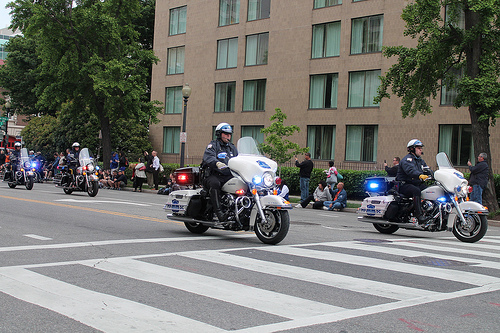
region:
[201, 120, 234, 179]
this is a policeman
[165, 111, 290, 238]
the policeman is on a motorcycle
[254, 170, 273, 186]
the front lights are on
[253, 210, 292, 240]
the whee is small in size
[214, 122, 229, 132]
the police is wearing a helmet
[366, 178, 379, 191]
the side light is on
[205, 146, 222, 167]
the jacket is black in color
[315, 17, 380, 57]
the windows are closed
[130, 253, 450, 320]
this is a zebra crossing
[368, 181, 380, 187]
the light is blue in color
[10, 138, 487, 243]
the men are on bikes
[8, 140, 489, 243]
the cops are on bikes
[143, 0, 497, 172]
the building has many windows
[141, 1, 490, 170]
the building is brown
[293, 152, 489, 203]
people take photos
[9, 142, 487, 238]
the bike lights are on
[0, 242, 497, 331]
the street has white lines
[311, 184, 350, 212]
people sit on the ground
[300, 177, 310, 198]
the man wears denim pants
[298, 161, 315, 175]
the man wears a black shirt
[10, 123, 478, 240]
police on motorcycles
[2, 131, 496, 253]
motorcycle cops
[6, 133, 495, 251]
four policemen on motorcycles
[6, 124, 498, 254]
people stand on the side of the road watching the motorcycle riders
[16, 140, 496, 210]
a crowd gathered on the sidewalk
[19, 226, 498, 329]
a crosswalk on the road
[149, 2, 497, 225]
a building next to the road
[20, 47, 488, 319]
the motorcycles have the lights on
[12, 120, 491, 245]
red, white and blue lights on the motorcycles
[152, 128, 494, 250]
the front two motorcycles are white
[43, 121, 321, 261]
police riding motorcycles on a street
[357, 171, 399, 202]
blue light on motorcycle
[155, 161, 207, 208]
red light on motorcycle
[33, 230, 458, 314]
white lines on street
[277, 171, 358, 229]
people sitting on curb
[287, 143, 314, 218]
man taking picture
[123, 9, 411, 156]
beige building in background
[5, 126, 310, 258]
police motorcycles are in a line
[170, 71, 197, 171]
street lamp is not on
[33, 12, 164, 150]
tree on sidewalk in distance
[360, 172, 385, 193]
Blue light on back of police motorcycle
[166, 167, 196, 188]
Red light on back of police motorcycle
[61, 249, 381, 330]
White lines on road for crosswalk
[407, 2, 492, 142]
Tall tree in front of building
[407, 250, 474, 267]
Steel man hole cover in middle of crosswalk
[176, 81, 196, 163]
Black pole with a light and a sign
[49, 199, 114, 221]
Yellow line located in middle of road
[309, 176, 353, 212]
People sitting on curb watching motorcycles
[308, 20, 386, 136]
Windows on front of brick building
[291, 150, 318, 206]
Man taking picture of motorcycles